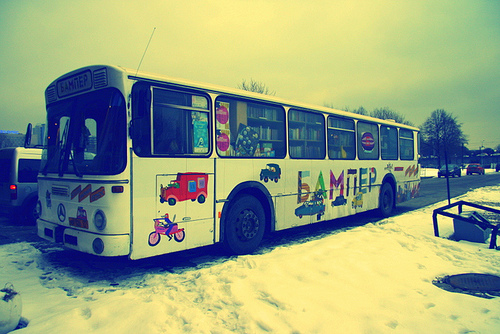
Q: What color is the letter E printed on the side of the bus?
A: Blue.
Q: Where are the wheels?
A: On the bus.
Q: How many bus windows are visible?
A: 8.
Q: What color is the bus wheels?
A: Black.